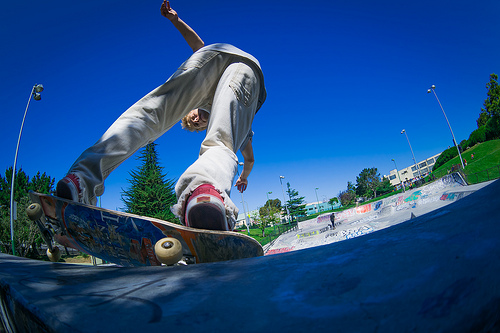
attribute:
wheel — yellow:
[155, 238, 182, 264]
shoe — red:
[184, 183, 228, 231]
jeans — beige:
[67, 50, 258, 228]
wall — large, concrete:
[0, 180, 497, 332]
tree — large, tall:
[120, 143, 179, 225]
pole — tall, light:
[425, 84, 465, 171]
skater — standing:
[329, 212, 335, 229]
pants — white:
[70, 49, 259, 228]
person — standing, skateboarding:
[328, 213, 335, 229]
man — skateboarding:
[58, 1, 268, 231]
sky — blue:
[1, 2, 498, 211]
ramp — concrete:
[0, 170, 498, 333]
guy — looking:
[59, 2, 268, 232]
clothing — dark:
[329, 213, 337, 229]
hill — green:
[425, 139, 499, 182]